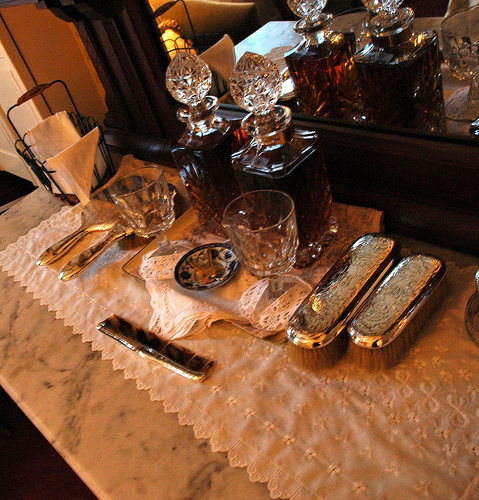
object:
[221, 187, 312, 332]
cup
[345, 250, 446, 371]
brush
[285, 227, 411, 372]
brush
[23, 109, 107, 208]
napkin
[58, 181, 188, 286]
brush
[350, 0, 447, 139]
bottle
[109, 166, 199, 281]
glasses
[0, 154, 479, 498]
white napkin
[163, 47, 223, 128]
bottle toppers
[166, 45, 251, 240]
bottles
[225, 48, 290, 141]
toppers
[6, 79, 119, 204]
basket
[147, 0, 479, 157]
mirror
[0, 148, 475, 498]
dresser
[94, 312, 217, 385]
comb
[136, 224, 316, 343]
napkin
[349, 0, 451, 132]
bottles mirror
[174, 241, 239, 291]
saucer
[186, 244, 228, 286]
keys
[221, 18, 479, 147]
dresser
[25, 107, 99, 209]
cloth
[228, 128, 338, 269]
alcohol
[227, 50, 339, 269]
bottle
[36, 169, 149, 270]
mirror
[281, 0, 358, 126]
bottle reflection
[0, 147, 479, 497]
top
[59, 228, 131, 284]
handle